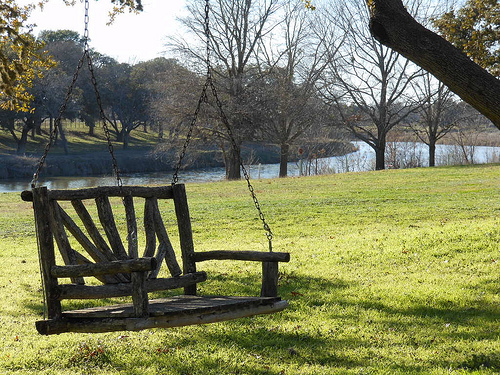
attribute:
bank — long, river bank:
[0, 139, 357, 176]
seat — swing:
[16, 7, 293, 342]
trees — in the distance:
[214, 13, 438, 217]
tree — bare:
[286, 1, 446, 169]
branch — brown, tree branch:
[370, 1, 498, 116]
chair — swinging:
[19, 168, 302, 343]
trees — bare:
[198, 17, 305, 164]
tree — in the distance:
[68, 62, 114, 138]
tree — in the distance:
[96, 72, 150, 147]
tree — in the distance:
[136, 59, 183, 139]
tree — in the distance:
[389, 42, 457, 166]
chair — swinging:
[21, 179, 300, 335]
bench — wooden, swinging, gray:
[16, 164, 279, 327]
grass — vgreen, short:
[319, 215, 387, 259]